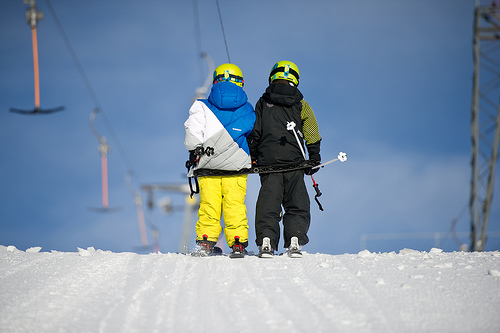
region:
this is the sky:
[332, 27, 447, 102]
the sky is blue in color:
[365, 54, 420, 98]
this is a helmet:
[218, 64, 240, 80]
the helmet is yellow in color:
[223, 61, 235, 70]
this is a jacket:
[217, 102, 242, 165]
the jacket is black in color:
[264, 117, 279, 150]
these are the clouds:
[350, 171, 403, 202]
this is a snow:
[223, 262, 380, 299]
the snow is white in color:
[303, 268, 365, 304]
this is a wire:
[53, 20, 104, 97]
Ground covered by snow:
[0, 243, 497, 330]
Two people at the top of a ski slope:
[183, 57, 321, 257]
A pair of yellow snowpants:
[195, 172, 250, 245]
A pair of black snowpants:
[253, 167, 312, 245]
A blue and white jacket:
[183, 83, 256, 171]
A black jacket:
[248, 80, 322, 172]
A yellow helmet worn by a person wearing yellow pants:
[211, 62, 245, 86]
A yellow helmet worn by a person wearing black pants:
[268, 59, 300, 85]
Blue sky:
[0, 0, 499, 253]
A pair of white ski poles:
[286, 120, 348, 214]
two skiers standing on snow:
[169, 47, 368, 264]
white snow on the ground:
[20, 263, 439, 313]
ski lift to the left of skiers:
[7, 3, 159, 236]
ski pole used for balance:
[309, 143, 361, 175]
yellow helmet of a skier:
[266, 49, 311, 91]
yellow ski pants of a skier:
[188, 176, 268, 256]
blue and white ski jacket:
[186, 84, 263, 182]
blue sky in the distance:
[309, 5, 456, 78]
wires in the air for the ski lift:
[177, 3, 254, 60]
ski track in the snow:
[159, 266, 191, 328]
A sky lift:
[68, 66, 172, 238]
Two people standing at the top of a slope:
[164, 49, 323, 276]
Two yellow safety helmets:
[185, 56, 326, 105]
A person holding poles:
[251, 54, 359, 280]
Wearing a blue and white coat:
[176, 80, 264, 190]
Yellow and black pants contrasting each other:
[185, 168, 313, 256]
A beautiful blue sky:
[274, 15, 480, 163]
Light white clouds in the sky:
[329, 139, 482, 233]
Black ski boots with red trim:
[185, 226, 265, 259]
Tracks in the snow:
[144, 249, 374, 327]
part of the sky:
[365, 9, 429, 78]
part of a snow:
[345, 268, 391, 321]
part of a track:
[285, 209, 300, 241]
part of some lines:
[273, 262, 313, 307]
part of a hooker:
[328, 134, 353, 176]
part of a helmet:
[278, 59, 300, 80]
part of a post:
[461, 155, 481, 240]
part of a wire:
[59, 50, 96, 100]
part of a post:
[177, 213, 200, 248]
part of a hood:
[208, 90, 241, 114]